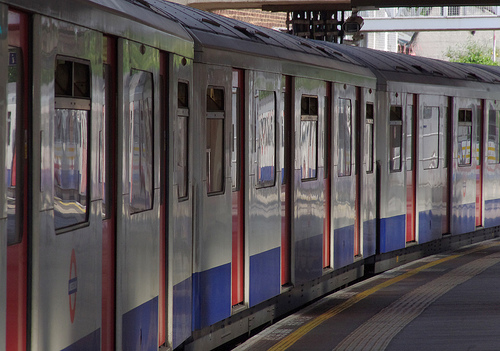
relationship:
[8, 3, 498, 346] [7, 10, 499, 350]
train has doors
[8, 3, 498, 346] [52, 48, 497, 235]
train has window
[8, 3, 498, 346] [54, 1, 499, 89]
train has roof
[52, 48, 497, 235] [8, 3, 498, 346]
window of a train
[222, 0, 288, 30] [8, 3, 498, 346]
building behind train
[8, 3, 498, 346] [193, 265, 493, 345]
train around curve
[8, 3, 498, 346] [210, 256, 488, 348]
train on track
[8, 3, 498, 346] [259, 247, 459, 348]
train on track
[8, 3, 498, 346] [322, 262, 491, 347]
train next sidewalk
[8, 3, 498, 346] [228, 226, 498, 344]
train next to sidewalk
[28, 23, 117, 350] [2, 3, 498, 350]
door on subway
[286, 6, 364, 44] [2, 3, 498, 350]
equipment to run subway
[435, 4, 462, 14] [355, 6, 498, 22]
window in a nearby building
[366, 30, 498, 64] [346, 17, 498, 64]
siding on nearby building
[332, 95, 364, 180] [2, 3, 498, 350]
window in subway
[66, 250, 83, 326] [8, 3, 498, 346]
logo on train